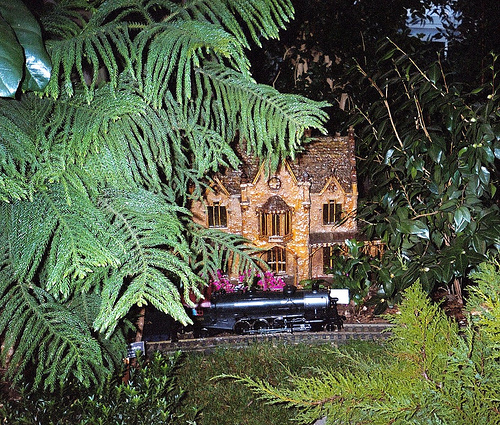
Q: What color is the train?
A: Black.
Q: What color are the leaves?
A: Green.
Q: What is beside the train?
A: A building.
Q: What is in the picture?
A: A model set.